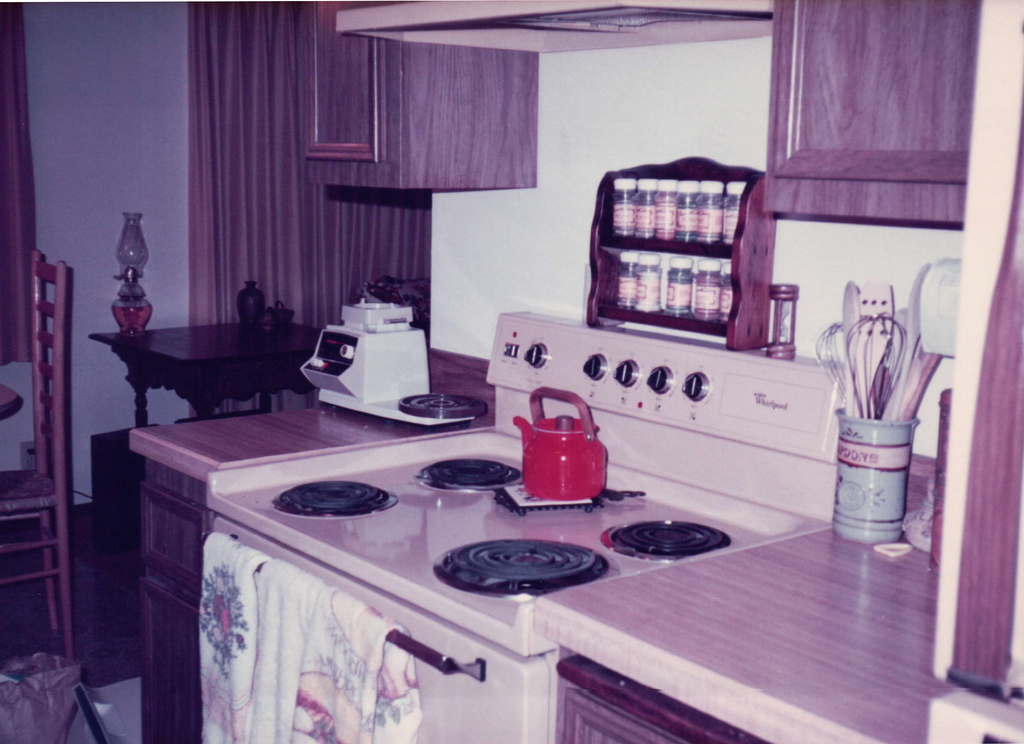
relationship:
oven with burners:
[212, 244, 826, 722] [288, 453, 755, 620]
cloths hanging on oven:
[197, 533, 425, 744] [206, 510, 567, 744]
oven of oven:
[206, 510, 567, 744] [196, 497, 570, 740]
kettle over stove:
[512, 386, 610, 500] [246, 450, 739, 625]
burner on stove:
[423, 450, 512, 485] [244, 437, 754, 619]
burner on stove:
[600, 508, 747, 565] [244, 437, 754, 619]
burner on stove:
[455, 534, 596, 587] [244, 437, 754, 619]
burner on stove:
[280, 472, 399, 514] [244, 437, 754, 619]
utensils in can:
[803, 281, 948, 416] [827, 409, 912, 533]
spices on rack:
[609, 173, 743, 325] [587, 147, 769, 349]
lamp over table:
[106, 210, 145, 331] [73, 307, 342, 405]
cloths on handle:
[197, 533, 425, 744] [381, 630, 490, 686]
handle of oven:
[391, 625, 500, 695] [196, 497, 570, 740]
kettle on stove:
[512, 385, 601, 500] [259, 437, 765, 608]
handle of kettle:
[525, 381, 593, 431] [509, 379, 607, 507]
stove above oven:
[227, 441, 755, 645] [196, 497, 570, 740]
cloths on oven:
[197, 521, 426, 738] [197, 504, 558, 632]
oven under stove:
[196, 497, 570, 740] [199, 301, 850, 738]